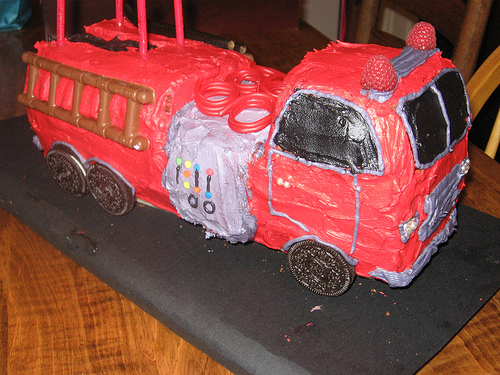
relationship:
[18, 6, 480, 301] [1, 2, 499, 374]
cake on table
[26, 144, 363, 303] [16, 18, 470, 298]
tires on fire truck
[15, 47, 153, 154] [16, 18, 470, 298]
frosting ladder on fire truck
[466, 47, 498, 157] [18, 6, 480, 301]
chair next to cake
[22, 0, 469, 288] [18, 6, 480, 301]
frosting on a cake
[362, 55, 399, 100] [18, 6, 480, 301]
berry on cake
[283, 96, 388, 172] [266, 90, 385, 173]
window has frosting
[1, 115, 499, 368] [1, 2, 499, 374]
platform on table